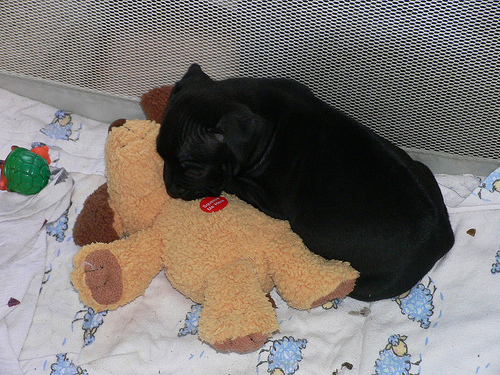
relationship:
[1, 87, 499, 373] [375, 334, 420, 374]
blanket has sheep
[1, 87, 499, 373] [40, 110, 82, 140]
blanket has sheep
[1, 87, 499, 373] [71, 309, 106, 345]
blanket has sheep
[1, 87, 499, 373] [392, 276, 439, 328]
blanket has sheep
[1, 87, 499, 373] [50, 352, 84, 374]
blanket has sheep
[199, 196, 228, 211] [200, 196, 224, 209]
tag says squeeze me here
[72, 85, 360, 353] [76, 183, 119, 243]
stuffed dog has ears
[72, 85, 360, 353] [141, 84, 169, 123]
stuffed dog has ears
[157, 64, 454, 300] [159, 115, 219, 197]
puppy has wrinkly face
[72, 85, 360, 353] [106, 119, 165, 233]
teddy bear has head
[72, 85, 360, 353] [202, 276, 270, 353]
teddy bear has leg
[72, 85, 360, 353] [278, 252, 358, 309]
teddy bear has leg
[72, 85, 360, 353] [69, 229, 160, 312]
teddy bear has arm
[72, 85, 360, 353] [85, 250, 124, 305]
teddy bear has paw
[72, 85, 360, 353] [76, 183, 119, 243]
puppy has ears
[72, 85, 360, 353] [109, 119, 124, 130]
teddy bear has nose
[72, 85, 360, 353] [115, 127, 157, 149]
teddy bear has mouth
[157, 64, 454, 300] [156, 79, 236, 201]
puppy has head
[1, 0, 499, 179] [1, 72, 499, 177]
net has edge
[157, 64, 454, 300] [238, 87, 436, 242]
dog has back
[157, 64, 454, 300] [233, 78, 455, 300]
dog has body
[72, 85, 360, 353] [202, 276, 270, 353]
doll has leg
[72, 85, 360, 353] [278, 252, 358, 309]
doll has leg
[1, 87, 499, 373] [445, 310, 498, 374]
sheet has part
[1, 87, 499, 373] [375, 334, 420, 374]
bed has design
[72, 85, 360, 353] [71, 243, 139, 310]
doll has hand